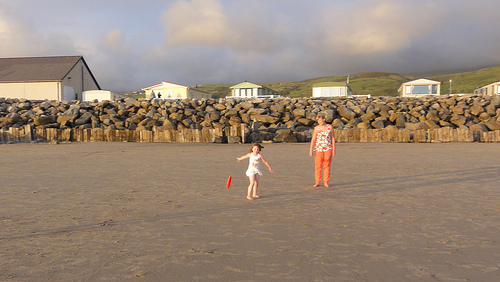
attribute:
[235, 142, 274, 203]
girl — barefoot, little, small, playing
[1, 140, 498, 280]
sand — gray, brown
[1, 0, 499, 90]
sky — blue, cloudy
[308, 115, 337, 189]
woman — older, barefoot, wearing orange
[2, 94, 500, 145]
seawall — rocky, piled, stone, made of stones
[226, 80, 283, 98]
buildings — small, in the background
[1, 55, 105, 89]
roof — brown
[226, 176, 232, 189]
frisbee — red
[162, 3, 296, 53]
cloud — wispy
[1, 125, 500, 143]
fence — small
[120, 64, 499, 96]
hill — green